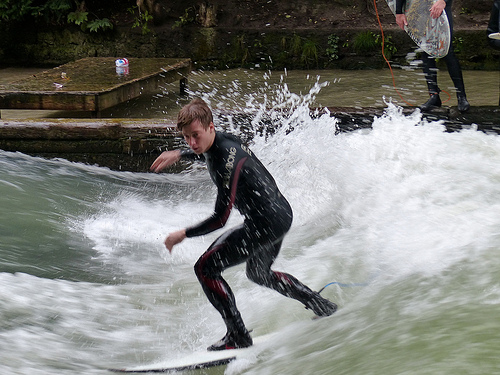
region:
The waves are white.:
[337, 139, 470, 273]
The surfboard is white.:
[86, 279, 378, 373]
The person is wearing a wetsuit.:
[96, 90, 358, 370]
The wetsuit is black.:
[80, 96, 351, 373]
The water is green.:
[10, 178, 85, 270]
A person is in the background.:
[359, 0, 488, 150]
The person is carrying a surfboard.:
[360, 0, 485, 132]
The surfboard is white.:
[361, 0, 478, 132]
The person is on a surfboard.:
[93, 92, 383, 371]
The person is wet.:
[86, 83, 376, 373]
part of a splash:
[294, 110, 371, 197]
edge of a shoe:
[216, 330, 244, 346]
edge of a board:
[204, 348, 226, 368]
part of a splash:
[336, 248, 399, 345]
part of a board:
[197, 331, 224, 364]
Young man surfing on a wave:
[83, 85, 366, 374]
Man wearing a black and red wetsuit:
[148, 93, 350, 357]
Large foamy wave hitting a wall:
[248, 60, 473, 364]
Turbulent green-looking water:
[4, 152, 149, 363]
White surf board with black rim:
[89, 298, 354, 373]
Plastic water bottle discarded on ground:
[111, 53, 132, 70]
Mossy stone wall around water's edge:
[3, 97, 495, 184]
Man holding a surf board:
[371, 0, 481, 122]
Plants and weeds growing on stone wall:
[1, 9, 367, 71]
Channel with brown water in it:
[5, 47, 490, 127]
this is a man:
[148, 99, 341, 352]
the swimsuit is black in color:
[237, 171, 262, 203]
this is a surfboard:
[116, 351, 235, 371]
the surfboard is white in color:
[166, 356, 184, 366]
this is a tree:
[9, 4, 111, 28]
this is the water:
[21, 195, 158, 314]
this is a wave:
[356, 192, 465, 335]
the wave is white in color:
[338, 192, 443, 245]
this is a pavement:
[107, 125, 135, 157]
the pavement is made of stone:
[339, 76, 362, 103]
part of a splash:
[296, 46, 376, 163]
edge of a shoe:
[213, 341, 228, 354]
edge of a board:
[199, 350, 219, 367]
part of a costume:
[268, 245, 289, 280]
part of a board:
[199, 348, 220, 370]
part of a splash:
[343, 277, 392, 334]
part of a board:
[190, 336, 217, 366]